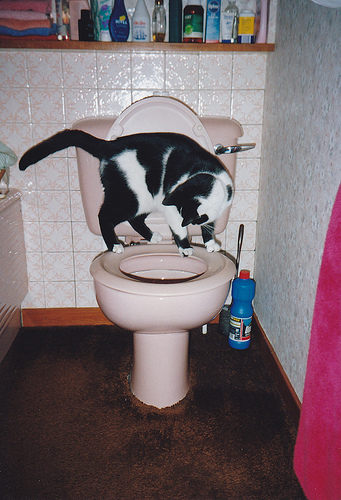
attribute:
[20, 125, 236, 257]
cat — black, white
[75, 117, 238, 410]
toilet — pink, porcelain, light pink, off white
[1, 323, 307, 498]
floor — brown, carpeted, dark brown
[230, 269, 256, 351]
bottle — blue, toilet cleaner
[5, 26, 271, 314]
tiles — pink, white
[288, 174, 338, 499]
towel — pink, red, folded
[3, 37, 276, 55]
shelf — brown, wooden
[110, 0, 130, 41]
bottle — blue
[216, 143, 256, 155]
handle — silver, metal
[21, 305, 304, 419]
baseboard — brown, wooden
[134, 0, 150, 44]
bottle — aftershave, old spice, white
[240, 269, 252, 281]
cap — red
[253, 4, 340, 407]
wallpaper — floral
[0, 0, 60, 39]
towels — folded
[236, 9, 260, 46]
powder bottle — white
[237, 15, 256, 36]
label — yellow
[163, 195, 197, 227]
ears — black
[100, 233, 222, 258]
paws — white